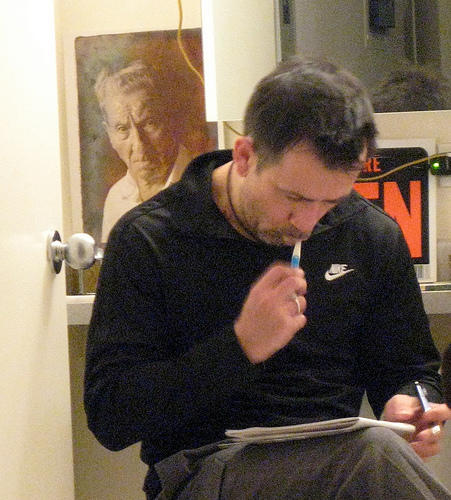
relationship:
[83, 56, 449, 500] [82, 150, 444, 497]
guy wearing black shirt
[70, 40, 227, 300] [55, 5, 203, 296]
poster on wall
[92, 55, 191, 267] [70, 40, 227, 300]
man in poster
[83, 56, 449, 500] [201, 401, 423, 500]
guy looking at papers laying on h lap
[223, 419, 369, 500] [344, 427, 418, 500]
pad of paper on mans knee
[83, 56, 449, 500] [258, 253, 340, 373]
guy with brown hair brushing h teeth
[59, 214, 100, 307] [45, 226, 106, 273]
silver colored door handle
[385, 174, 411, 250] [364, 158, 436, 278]
"open" sign with orange lettering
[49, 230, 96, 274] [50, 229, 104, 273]
silver metal door door handle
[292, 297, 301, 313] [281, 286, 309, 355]
ring on finger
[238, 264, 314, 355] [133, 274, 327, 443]
hand of a person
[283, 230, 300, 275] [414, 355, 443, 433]
pen used for writing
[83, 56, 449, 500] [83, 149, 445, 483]
guy wearing black shirt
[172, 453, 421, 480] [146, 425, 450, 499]
pair of grey pants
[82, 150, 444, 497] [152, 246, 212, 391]
black shirt black in color